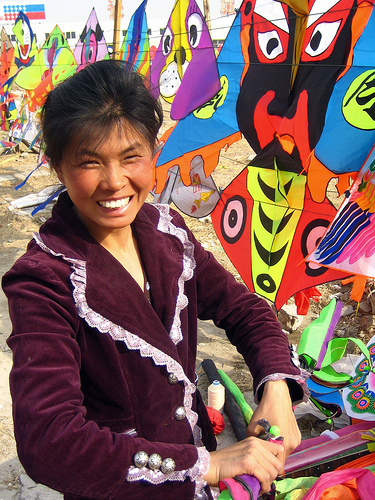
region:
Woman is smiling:
[1, 49, 325, 497]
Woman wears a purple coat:
[2, 49, 320, 499]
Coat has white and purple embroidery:
[4, 192, 320, 498]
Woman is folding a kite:
[2, 0, 322, 493]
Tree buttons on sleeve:
[130, 445, 176, 475]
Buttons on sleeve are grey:
[129, 444, 174, 474]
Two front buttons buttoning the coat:
[162, 367, 192, 419]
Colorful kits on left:
[5, 11, 373, 152]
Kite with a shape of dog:
[131, 3, 224, 119]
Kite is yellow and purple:
[145, 2, 227, 116]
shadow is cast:
[201, 315, 248, 414]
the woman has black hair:
[20, 9, 186, 249]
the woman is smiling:
[31, 20, 217, 231]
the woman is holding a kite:
[52, 203, 325, 494]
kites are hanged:
[157, 10, 372, 221]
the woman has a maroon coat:
[13, 167, 284, 497]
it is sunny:
[13, 27, 374, 374]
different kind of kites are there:
[9, 17, 366, 243]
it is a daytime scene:
[0, 35, 368, 379]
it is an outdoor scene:
[3, 20, 374, 288]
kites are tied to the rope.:
[23, 12, 338, 75]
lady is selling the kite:
[37, 19, 297, 239]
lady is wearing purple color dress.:
[60, 344, 113, 393]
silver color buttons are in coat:
[132, 450, 182, 479]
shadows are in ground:
[5, 177, 38, 234]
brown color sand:
[8, 162, 36, 212]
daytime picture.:
[16, 61, 330, 335]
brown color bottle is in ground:
[204, 373, 247, 431]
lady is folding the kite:
[197, 382, 315, 486]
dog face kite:
[159, 20, 218, 107]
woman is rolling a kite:
[0, 57, 310, 499]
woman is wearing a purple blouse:
[7, 185, 306, 499]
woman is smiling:
[91, 191, 139, 216]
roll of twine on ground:
[197, 374, 232, 415]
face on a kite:
[200, 133, 366, 310]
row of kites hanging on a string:
[1, 0, 373, 210]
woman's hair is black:
[35, 54, 164, 180]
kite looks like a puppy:
[132, 0, 235, 117]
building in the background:
[5, 15, 305, 61]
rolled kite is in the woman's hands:
[213, 413, 374, 497]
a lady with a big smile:
[23, 49, 188, 278]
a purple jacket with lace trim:
[3, 191, 304, 496]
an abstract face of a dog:
[141, 2, 220, 122]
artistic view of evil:
[227, 2, 364, 160]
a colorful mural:
[11, 0, 369, 123]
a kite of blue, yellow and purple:
[150, 7, 245, 166]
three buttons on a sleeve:
[124, 447, 182, 478]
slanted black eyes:
[242, 13, 346, 66]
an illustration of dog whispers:
[145, 51, 203, 104]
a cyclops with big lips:
[6, 6, 39, 66]